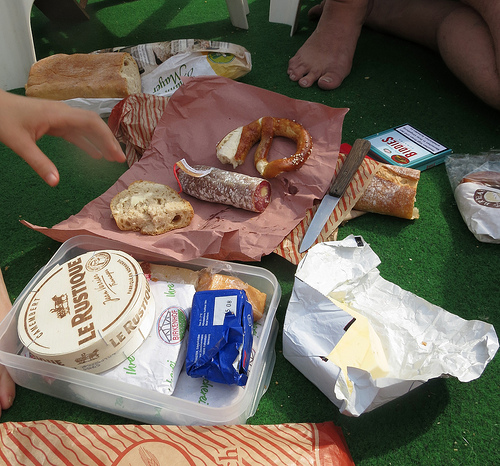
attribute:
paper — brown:
[20, 65, 352, 281]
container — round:
[13, 242, 173, 397]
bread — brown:
[217, 114, 315, 180]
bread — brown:
[107, 179, 195, 238]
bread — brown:
[349, 160, 423, 219]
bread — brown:
[24, 47, 141, 102]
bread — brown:
[191, 267, 267, 317]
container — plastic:
[174, 234, 324, 351]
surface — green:
[0, 0, 498, 465]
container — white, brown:
[16, 244, 157, 369]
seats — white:
[246, 8, 305, 28]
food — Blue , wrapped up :
[78, 75, 361, 252]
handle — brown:
[329, 136, 378, 196]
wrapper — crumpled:
[280, 232, 498, 416]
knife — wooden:
[299, 137, 372, 252]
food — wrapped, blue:
[185, 289, 254, 386]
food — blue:
[180, 277, 258, 393]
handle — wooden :
[312, 145, 371, 195]